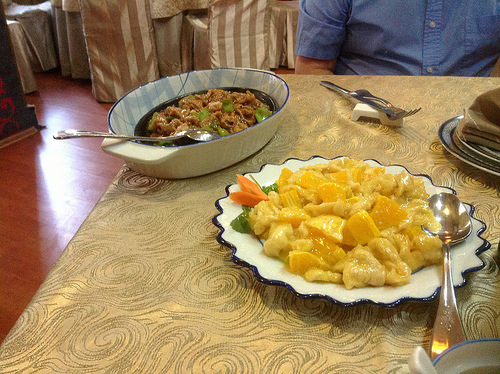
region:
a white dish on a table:
[211, 142, 491, 312]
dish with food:
[214, 146, 491, 310]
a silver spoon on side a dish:
[420, 178, 488, 356]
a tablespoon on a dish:
[422, 183, 477, 358]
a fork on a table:
[311, 65, 427, 125]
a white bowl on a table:
[91, 55, 296, 183]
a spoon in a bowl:
[37, 56, 291, 188]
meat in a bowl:
[93, 52, 294, 177]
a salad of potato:
[234, 154, 451, 287]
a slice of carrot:
[223, 168, 280, 217]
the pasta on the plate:
[223, 166, 495, 318]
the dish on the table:
[67, 60, 304, 190]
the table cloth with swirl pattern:
[70, 285, 200, 370]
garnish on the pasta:
[225, 204, 242, 225]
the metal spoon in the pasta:
[422, 182, 466, 371]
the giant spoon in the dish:
[35, 117, 224, 159]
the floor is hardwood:
[12, 153, 53, 233]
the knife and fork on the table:
[312, 77, 419, 144]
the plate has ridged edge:
[202, 159, 479, 324]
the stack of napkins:
[422, 106, 499, 127]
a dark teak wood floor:
[2, 155, 83, 226]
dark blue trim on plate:
[216, 232, 231, 252]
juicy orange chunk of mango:
[340, 206, 385, 236]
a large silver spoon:
[427, 190, 463, 345]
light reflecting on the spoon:
[435, 200, 466, 215]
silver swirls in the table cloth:
[57, 245, 152, 300]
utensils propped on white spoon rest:
[330, 75, 415, 125]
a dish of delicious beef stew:
[109, 74, 289, 161]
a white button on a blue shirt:
[426, 20, 443, 35]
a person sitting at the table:
[293, 2, 498, 80]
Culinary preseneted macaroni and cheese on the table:
[210, 152, 490, 314]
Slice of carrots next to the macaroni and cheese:
[225, 167, 272, 207]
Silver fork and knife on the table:
[307, 75, 425, 127]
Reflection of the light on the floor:
[31, 103, 93, 210]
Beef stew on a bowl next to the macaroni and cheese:
[94, 62, 293, 154]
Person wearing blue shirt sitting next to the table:
[296, 0, 498, 79]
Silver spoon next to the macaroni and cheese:
[423, 190, 473, 356]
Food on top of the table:
[99, 64, 495, 314]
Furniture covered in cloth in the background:
[10, 0, 295, 103]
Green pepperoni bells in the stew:
[221, 96, 235, 113]